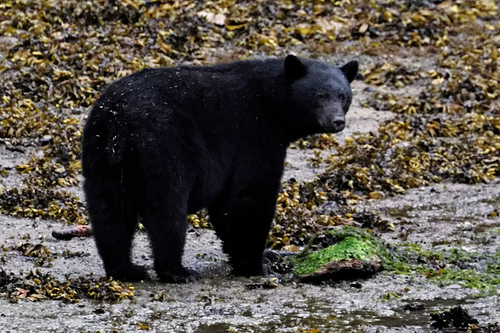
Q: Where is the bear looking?
A: At the camera.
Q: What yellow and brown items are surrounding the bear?
A: Leaves.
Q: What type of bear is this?
A: Black bear.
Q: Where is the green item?
A: In front of the bear.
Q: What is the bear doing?
A: Standing.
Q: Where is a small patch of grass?
A: Front of bear.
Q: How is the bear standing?
A: On all four legs.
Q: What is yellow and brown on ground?
A: Leaves and sticks.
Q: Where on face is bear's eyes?
A: Between ears and nose.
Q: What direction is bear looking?
A: Right.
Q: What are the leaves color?
A: Yellow and brown.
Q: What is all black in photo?
A: A bear.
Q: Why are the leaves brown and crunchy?
A: It's autumn.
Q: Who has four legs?
A: A bear.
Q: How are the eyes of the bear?
A: Open.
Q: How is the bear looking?
A: Backwards.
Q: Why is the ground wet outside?
A: Raining.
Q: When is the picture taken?
A: Daytime.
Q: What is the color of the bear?
A: Black.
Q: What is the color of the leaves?
A: Brown.